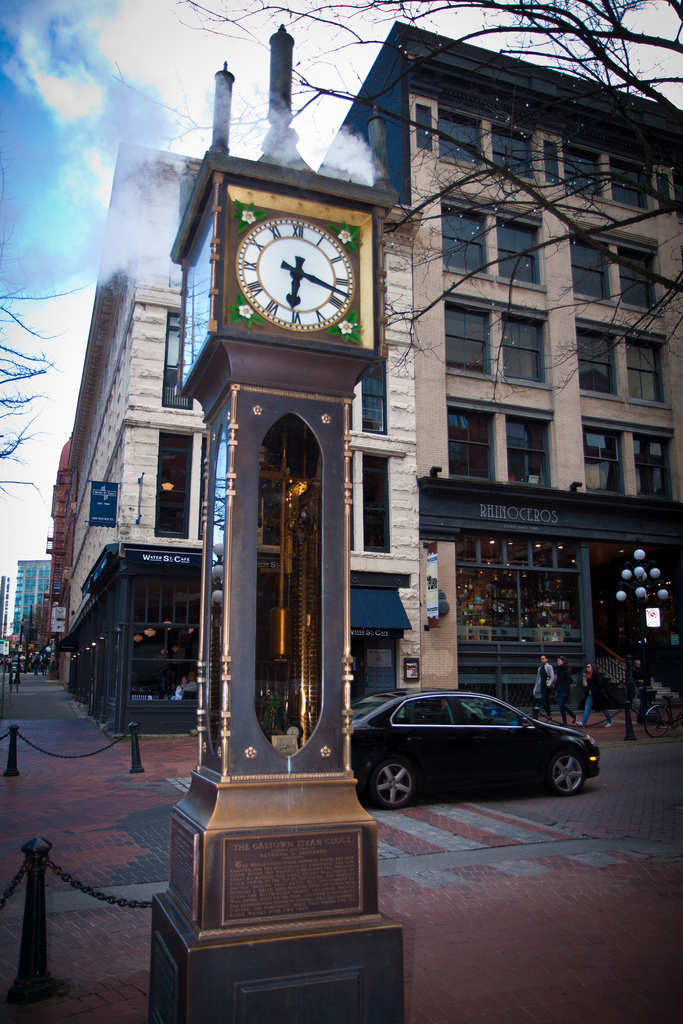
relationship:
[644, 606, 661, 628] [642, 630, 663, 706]
sign on pole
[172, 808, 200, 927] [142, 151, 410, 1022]
plaque on tower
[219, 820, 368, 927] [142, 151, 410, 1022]
plaque on tower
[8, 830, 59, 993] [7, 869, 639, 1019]
post on sidewalk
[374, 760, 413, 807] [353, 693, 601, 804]
rim on car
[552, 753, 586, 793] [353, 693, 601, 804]
rim on car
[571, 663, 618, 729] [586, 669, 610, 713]
woman wearing a black jacket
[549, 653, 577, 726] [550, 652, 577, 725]
woman wearing a black jacket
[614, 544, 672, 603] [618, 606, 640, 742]
lights on black pole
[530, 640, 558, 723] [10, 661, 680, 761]
man on sidewalk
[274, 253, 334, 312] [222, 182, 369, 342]
hands on clock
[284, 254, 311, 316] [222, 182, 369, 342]
hands on clock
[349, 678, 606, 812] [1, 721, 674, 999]
vehicle on street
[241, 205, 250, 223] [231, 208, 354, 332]
flower bordering clock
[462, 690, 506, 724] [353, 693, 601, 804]
window on car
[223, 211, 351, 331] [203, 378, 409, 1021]
clock on pedastal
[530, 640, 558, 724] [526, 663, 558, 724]
man wearing outfit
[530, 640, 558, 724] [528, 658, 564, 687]
man wearing jacket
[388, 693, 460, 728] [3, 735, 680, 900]
window in street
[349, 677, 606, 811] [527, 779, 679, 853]
vehicle in street.